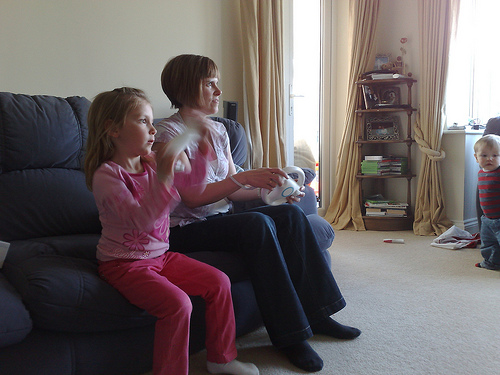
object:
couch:
[1, 90, 334, 354]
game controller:
[260, 166, 310, 206]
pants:
[106, 252, 242, 375]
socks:
[285, 311, 362, 371]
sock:
[205, 360, 264, 374]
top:
[88, 159, 204, 262]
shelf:
[353, 69, 422, 231]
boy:
[469, 132, 499, 274]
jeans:
[479, 217, 500, 269]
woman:
[163, 55, 366, 354]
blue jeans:
[181, 208, 342, 338]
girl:
[81, 85, 242, 364]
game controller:
[162, 123, 208, 185]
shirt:
[475, 167, 499, 217]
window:
[437, 2, 499, 132]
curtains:
[414, 0, 453, 235]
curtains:
[330, 2, 376, 229]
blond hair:
[471, 136, 499, 152]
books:
[360, 155, 412, 178]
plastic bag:
[429, 224, 482, 256]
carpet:
[345, 244, 476, 335]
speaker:
[223, 97, 241, 120]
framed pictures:
[360, 83, 403, 107]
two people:
[82, 53, 362, 371]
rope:
[413, 122, 441, 164]